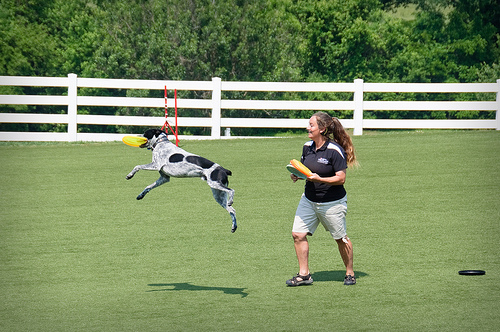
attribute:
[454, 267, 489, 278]
disc — black, laying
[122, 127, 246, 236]
dog — spotted, jumping, white, black, leaping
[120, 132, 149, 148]
frisbee — yellow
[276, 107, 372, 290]
woman — training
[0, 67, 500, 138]
fence — white, wooden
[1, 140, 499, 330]
grass — green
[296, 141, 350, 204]
shirt — black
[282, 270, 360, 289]
sandals — black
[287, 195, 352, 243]
shorts — tan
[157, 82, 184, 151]
jump — red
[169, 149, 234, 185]
spots — black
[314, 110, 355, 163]
hair — long